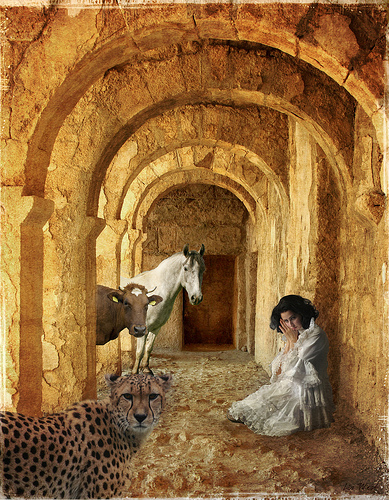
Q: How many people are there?
A: One.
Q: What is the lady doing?
A: Sitting.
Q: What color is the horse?
A: White.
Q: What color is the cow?
A: Brown.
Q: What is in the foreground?
A: A cheetah.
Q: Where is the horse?
A: Behind the cow.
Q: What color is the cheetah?
A: Orange and black.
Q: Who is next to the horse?
A: The cow.